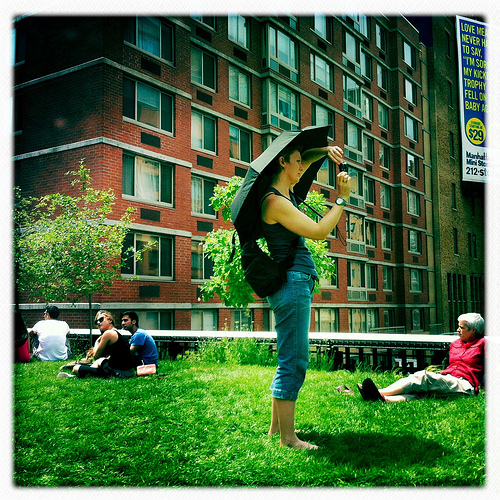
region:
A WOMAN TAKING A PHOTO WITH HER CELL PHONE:
[215, 110, 363, 465]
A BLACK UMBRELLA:
[220, 113, 356, 253]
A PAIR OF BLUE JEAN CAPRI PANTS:
[258, 262, 325, 417]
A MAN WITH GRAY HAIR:
[351, 302, 495, 397]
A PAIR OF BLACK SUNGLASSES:
[90, 312, 115, 330]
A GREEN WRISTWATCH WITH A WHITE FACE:
[330, 193, 350, 208]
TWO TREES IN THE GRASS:
[13, 153, 168, 373]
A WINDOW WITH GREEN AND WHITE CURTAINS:
[115, 141, 186, 211]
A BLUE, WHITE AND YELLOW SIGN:
[445, 10, 497, 185]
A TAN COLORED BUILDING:
[408, 10, 495, 349]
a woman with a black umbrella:
[201, 85, 366, 294]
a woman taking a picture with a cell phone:
[252, 135, 377, 250]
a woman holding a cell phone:
[223, 147, 365, 243]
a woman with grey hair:
[454, 295, 481, 390]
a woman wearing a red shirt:
[436, 300, 477, 422]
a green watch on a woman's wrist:
[294, 165, 369, 248]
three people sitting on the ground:
[40, 302, 172, 401]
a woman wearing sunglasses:
[76, 306, 116, 355]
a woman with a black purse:
[226, 139, 323, 321]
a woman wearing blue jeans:
[238, 104, 365, 475]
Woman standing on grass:
[233, 122, 350, 450]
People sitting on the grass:
[15, 304, 487, 402]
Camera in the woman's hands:
[338, 160, 349, 172]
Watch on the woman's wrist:
[334, 195, 344, 205]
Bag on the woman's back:
[226, 223, 297, 296]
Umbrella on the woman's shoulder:
[229, 124, 345, 244]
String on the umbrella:
[336, 226, 348, 246]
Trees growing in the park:
[12, 157, 334, 342]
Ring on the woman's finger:
[341, 177, 348, 182]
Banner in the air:
[455, 11, 488, 184]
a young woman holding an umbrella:
[209, 115, 361, 469]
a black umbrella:
[221, 119, 351, 228]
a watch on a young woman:
[335, 192, 346, 208]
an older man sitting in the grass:
[357, 302, 481, 409]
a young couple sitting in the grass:
[81, 302, 176, 378]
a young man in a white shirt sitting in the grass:
[26, 300, 83, 370]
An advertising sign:
[443, 21, 499, 190]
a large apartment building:
[126, 34, 421, 318]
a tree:
[33, 160, 143, 325]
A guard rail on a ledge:
[56, 325, 471, 367]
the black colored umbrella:
[212, 111, 325, 233]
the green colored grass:
[365, 426, 426, 468]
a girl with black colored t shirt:
[73, 304, 130, 382]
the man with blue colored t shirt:
[123, 308, 165, 380]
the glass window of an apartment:
[118, 76, 181, 135]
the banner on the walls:
[455, 20, 483, 190]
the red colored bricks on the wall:
[66, 90, 111, 119]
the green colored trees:
[24, 174, 131, 290]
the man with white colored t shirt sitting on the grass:
[29, 303, 70, 368]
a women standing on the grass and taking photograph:
[223, 108, 355, 458]